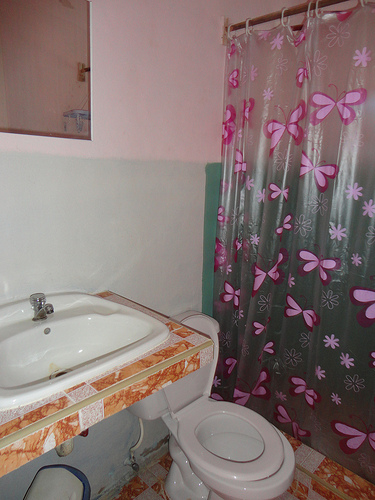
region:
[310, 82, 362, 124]
butterfly on the curtain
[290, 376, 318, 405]
butterfly pink and purple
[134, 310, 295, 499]
the toilet is white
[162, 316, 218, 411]
toilet lid is up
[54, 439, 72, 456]
the pipe is white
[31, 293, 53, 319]
the faucet of the sink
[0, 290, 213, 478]
sink has orange and white pattern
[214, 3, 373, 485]
shower curtain with butterflies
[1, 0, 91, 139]
a panel on the wall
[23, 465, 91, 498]
trash can on floor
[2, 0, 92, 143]
the mirror on the wall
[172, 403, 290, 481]
the seat of the toilet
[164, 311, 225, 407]
the lid of the toilet is up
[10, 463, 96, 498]
the waste bin below the sink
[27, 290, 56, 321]
the faucet over the sink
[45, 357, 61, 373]
the stain on the sink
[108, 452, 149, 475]
the valve on the wall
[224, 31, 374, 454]
butterflies on the shower curtain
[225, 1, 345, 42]
the shower rod on the wall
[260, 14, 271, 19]
SHOWER ROD MADE OUT OF WOOD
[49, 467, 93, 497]
TRASH CAN UNDER SINK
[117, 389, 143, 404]
COUNTER TOP MADE OF TILE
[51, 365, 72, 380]
DRAIN IN THE MIDDLE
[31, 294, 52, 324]
FAUCET ON THE SINK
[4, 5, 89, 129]
MIRROR ON THE WALL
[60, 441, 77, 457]
PIPE UNDER THE SINK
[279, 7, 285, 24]
HOOKS ON THE ROD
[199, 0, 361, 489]
shower curtain with pink butterflies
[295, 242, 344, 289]
pink butterfly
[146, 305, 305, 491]
white toilet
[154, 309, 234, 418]
open seat of toilet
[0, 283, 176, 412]
white sink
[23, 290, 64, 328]
faucet on white sink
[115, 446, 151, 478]
water knob under toilet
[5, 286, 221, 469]
orange and white sink counter top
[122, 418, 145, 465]
white pipe leading to toilet tank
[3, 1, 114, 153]
mirror above sink